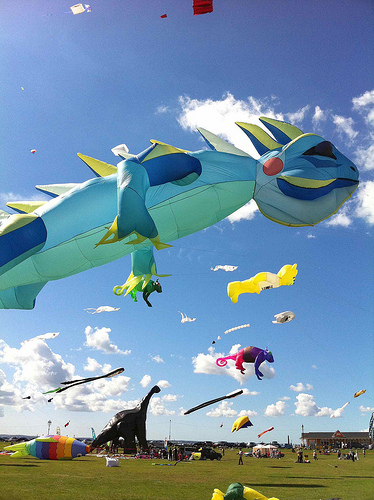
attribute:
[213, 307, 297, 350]
kite — in the picture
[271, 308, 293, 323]
kite — in the picture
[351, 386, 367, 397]
kite — in the picture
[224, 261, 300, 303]
kite — in the picture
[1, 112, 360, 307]
kite — dragon shaped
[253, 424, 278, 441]
kite — in the picture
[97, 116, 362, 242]
balloon — big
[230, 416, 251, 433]
kite — in the picture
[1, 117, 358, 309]
dinosaur — toy